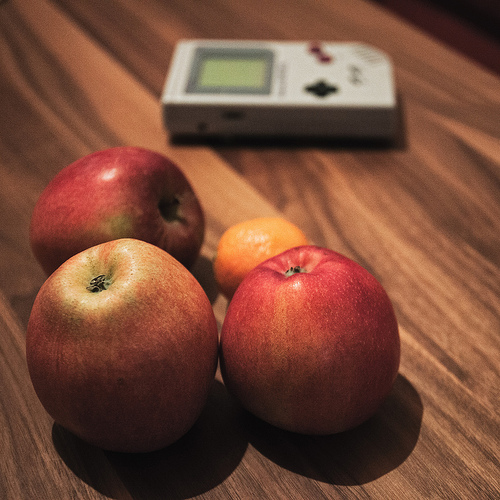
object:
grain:
[6, 92, 47, 156]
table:
[3, 1, 482, 222]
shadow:
[289, 424, 426, 482]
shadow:
[50, 379, 247, 500]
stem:
[285, 265, 305, 274]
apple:
[220, 245, 401, 440]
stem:
[85, 275, 120, 293]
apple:
[25, 237, 220, 455]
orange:
[212, 216, 315, 295]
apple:
[30, 145, 207, 277]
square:
[200, 49, 266, 95]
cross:
[304, 79, 341, 102]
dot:
[308, 44, 331, 67]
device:
[162, 38, 400, 142]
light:
[101, 164, 120, 183]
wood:
[431, 52, 500, 369]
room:
[6, 5, 498, 496]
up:
[134, 12, 195, 25]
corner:
[362, 42, 390, 57]